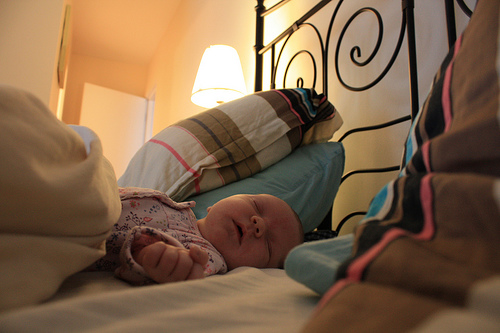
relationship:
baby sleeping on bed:
[107, 169, 314, 291] [32, 97, 496, 329]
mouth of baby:
[228, 213, 264, 255] [91, 155, 355, 297]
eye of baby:
[248, 196, 264, 216] [79, 186, 307, 285]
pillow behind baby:
[116, 88, 344, 203] [106, 182, 328, 298]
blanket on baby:
[5, 78, 122, 315] [109, 176, 314, 286]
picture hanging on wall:
[53, 10, 76, 87] [4, 7, 48, 66]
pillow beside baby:
[117, 87, 354, 256] [79, 186, 307, 285]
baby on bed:
[79, 186, 307, 285] [1, 233, 496, 331]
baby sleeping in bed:
[79, 186, 307, 285] [1, 247, 498, 329]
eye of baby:
[248, 196, 264, 216] [109, 176, 314, 286]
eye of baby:
[265, 238, 277, 263] [109, 176, 314, 286]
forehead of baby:
[258, 191, 301, 273] [109, 176, 314, 286]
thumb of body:
[185, 240, 212, 266] [111, 167, 336, 281]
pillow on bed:
[116, 88, 344, 203] [3, 17, 498, 331]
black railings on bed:
[253, 0, 479, 240] [3, 17, 498, 331]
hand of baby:
[134, 238, 209, 283] [86, 176, 311, 286]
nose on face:
[250, 215, 273, 233] [206, 191, 306, 271]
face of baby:
[206, 191, 306, 271] [79, 186, 307, 285]